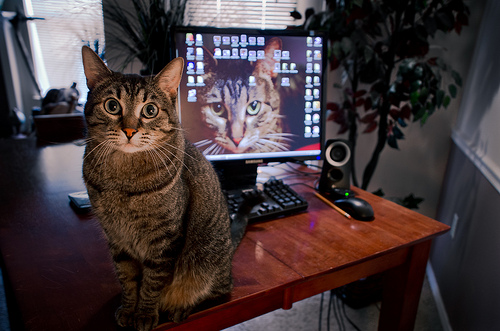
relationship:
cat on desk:
[80, 35, 229, 312] [289, 229, 355, 269]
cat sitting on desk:
[80, 35, 229, 312] [289, 229, 355, 269]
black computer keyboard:
[241, 187, 298, 215] [223, 180, 301, 214]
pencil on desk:
[300, 179, 352, 224] [289, 229, 355, 269]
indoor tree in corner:
[330, 3, 434, 164] [324, 4, 499, 263]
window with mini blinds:
[186, 5, 319, 22] [185, 3, 328, 45]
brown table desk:
[267, 215, 365, 270] [289, 229, 355, 269]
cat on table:
[80, 35, 229, 312] [261, 238, 324, 269]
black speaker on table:
[321, 135, 364, 185] [261, 238, 324, 269]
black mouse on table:
[334, 193, 372, 226] [289, 229, 355, 269]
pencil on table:
[300, 179, 352, 224] [261, 238, 324, 269]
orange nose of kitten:
[124, 121, 137, 136] [80, 35, 229, 312]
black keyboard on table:
[241, 187, 298, 215] [271, 223, 336, 292]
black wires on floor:
[311, 289, 365, 330] [298, 307, 385, 330]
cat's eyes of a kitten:
[102, 94, 126, 120] [80, 35, 229, 312]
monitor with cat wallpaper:
[182, 27, 329, 157] [192, 52, 273, 138]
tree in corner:
[330, 3, 434, 164] [324, 4, 499, 263]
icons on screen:
[186, 44, 307, 124] [182, 27, 329, 157]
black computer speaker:
[182, 27, 329, 157] [317, 128, 368, 211]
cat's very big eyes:
[80, 35, 229, 312] [90, 96, 176, 126]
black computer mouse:
[182, 27, 329, 157] [334, 193, 372, 226]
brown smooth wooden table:
[267, 215, 365, 270] [261, 238, 324, 269]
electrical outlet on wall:
[445, 207, 472, 242] [427, 166, 494, 277]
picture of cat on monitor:
[186, 44, 307, 124] [182, 27, 329, 157]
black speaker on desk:
[321, 135, 364, 185] [289, 229, 355, 269]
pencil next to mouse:
[300, 179, 352, 224] [342, 191, 359, 229]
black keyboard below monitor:
[241, 187, 298, 215] [182, 27, 329, 157]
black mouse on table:
[334, 193, 372, 226] [261, 238, 324, 269]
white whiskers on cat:
[85, 119, 184, 159] [80, 35, 229, 312]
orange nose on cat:
[124, 121, 137, 136] [80, 35, 229, 312]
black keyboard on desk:
[241, 187, 298, 215] [289, 229, 355, 269]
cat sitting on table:
[80, 35, 229, 312] [261, 238, 324, 269]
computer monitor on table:
[169, 29, 295, 261] [261, 238, 324, 269]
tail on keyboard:
[235, 194, 264, 225] [223, 180, 301, 214]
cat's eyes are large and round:
[102, 94, 169, 137] [105, 99, 163, 119]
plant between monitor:
[304, 6, 455, 209] [182, 27, 329, 157]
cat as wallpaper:
[182, 27, 329, 157] [192, 52, 273, 138]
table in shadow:
[261, 238, 324, 269] [16, 149, 94, 292]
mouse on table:
[336, 191, 376, 220] [0, 139, 452, 330]